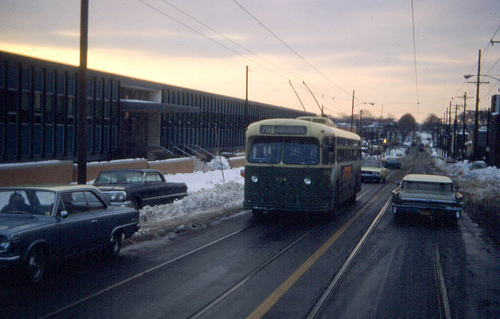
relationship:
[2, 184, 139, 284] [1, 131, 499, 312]
car on street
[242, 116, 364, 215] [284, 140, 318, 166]
bus has a window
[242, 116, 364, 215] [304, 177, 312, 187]
bus has a headlight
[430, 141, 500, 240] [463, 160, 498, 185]
snow in a pile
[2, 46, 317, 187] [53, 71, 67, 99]
building has a window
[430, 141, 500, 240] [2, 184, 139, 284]
snow on a car